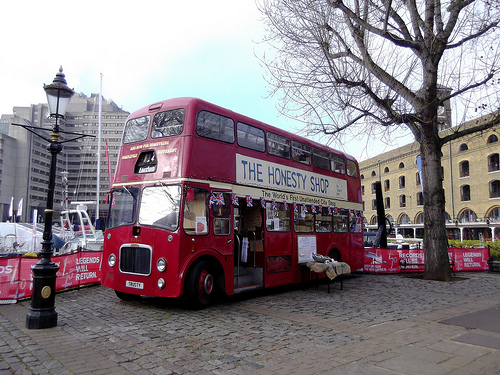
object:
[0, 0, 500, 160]
sky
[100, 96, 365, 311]
bus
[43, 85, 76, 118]
lamp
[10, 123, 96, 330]
post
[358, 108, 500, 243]
building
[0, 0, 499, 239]
background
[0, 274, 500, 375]
ground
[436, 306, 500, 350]
blocks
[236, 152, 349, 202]
sign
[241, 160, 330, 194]
lettering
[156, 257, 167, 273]
headlight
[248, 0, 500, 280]
tree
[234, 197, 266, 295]
door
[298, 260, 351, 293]
table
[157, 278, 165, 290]
light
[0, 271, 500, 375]
street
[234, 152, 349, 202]
banner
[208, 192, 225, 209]
flag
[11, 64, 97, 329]
streetlight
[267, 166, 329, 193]
hoesty shop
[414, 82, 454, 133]
tower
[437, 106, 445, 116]
clock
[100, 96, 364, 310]
double decker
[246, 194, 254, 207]
flags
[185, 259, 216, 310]
wheel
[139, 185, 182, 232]
windshield